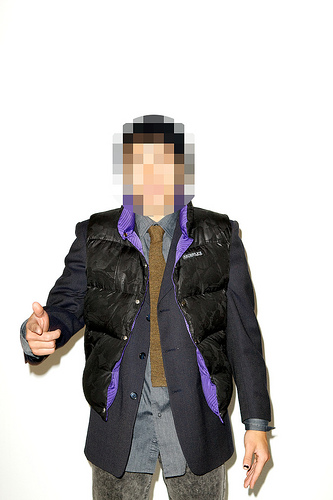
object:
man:
[20, 113, 274, 499]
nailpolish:
[243, 464, 251, 468]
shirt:
[125, 213, 186, 479]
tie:
[146, 224, 169, 390]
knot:
[146, 224, 167, 245]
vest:
[82, 201, 233, 423]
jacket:
[24, 216, 271, 477]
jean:
[91, 456, 225, 500]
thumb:
[241, 443, 253, 472]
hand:
[24, 302, 62, 358]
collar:
[131, 209, 178, 238]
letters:
[186, 254, 190, 259]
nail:
[243, 463, 249, 466]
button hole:
[157, 308, 173, 313]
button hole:
[163, 343, 180, 355]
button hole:
[169, 387, 182, 396]